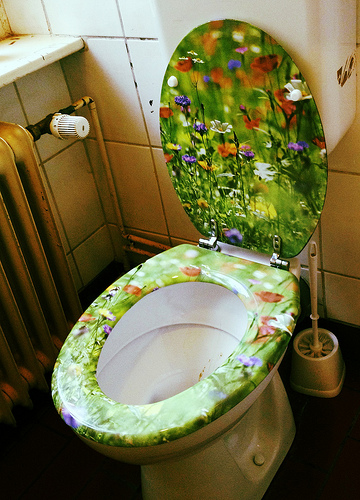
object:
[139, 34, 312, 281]
garden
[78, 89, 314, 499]
toilet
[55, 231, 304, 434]
seat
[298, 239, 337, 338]
brush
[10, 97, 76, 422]
radiator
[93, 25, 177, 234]
tile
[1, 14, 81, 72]
counter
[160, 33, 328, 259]
flowers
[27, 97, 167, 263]
pipes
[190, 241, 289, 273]
hinges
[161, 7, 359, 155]
tank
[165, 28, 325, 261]
lid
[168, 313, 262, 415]
stain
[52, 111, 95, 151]
vent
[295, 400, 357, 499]
floor